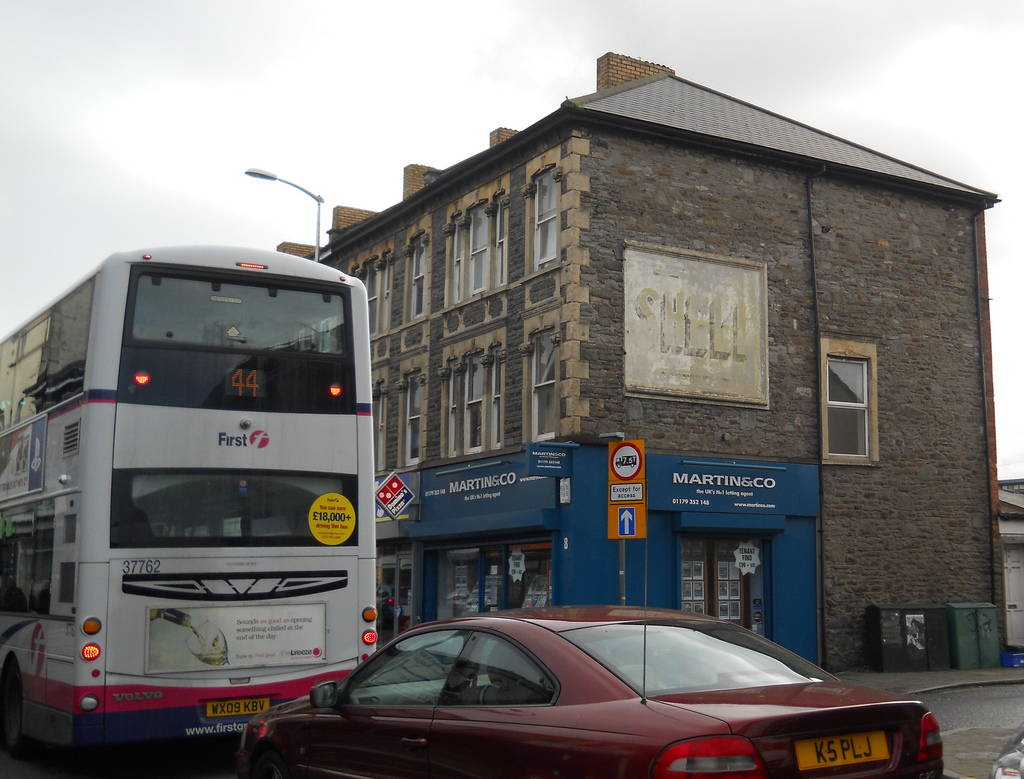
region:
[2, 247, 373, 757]
The double decker bus.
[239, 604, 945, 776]
The red saloon sedan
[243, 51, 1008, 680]
The tall office block.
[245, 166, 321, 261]
The high street lighting.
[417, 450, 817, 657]
The blue painted shop establishment.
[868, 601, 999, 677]
The litter bins on the right.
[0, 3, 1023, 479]
A sparsely clouded sky.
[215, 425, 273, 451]
The bus company's name and logo.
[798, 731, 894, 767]
The car's plate numbers.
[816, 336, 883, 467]
window on the side of the building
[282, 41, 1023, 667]
building is made of dark brick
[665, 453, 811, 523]
white writing on a blue background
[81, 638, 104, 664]
red light on the back of the bus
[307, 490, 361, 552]
yellow sign on the back of the bus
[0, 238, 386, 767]
double decker white bus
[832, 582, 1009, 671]
trash cans on the side of the building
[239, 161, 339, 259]
top of a street light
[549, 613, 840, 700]
window on the back of the car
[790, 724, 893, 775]
a bright yellow european license plate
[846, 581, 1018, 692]
a few locked, metal structures against wall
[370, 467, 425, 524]
a three dimensional restaurant sign on wall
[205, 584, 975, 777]
a small red sedan behind a bus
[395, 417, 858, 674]
a store with two wall painted bright blue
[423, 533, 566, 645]
a store front window with a white sign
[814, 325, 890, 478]
a narrow window in a brick building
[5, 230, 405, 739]
a double decker city bus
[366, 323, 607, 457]
a row of tall, narrow windows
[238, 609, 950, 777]
red parked car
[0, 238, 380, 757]
double decker bus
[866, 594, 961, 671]
black dumpster with poster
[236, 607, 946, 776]
red car with orange license plate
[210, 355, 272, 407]
orange and black digital display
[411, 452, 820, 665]
blue painted storefront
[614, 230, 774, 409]
faded large sign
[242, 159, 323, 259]
tall white streetlamp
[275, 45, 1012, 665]
tan chimneys on top of brick building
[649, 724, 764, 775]
Tail light of a car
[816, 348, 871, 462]
Window of a building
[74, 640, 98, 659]
Tail light of a bus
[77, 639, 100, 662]
Tail light of a white bus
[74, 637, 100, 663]
Tail light of a double decker bus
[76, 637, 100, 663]
Tail light of a white double decker bus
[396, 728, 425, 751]
Handle of a maroon car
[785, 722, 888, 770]
License plate of a car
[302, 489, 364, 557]
A yellow circle on the back of bus.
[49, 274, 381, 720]
A bus in front of the car.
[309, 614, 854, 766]
The car is burgundy.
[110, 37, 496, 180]
The sky has clouds.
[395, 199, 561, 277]
Windows in the front of the building.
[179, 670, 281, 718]
The license plate on the bus.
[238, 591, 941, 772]
a red car in street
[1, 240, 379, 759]
a public service bus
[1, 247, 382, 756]
a double decker bus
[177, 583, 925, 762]
red colored sedan on street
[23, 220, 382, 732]
white and red colored double decker bus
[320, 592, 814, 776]
the car is moving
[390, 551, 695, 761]
the car is red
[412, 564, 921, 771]
the car is sedan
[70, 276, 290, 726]
the bus is tall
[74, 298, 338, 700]
the bus is double decker